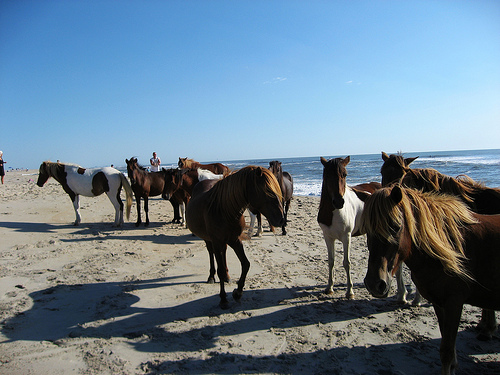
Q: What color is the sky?
A: Blue.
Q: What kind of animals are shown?
A: Horses.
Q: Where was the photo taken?
A: On the beach.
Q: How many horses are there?
A: Ten.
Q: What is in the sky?
A: Nothing.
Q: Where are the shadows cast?
A: To the left.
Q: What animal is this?
A: Horse.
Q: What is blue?
A: Water.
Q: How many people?
A: One.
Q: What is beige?
A: Sand.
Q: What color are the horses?
A: Brown and white.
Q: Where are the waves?
A: In the ocean.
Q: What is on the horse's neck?
A: Mane.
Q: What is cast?
A: Shadows.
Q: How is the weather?
A: Clear.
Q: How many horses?
A: 8.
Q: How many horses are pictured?
A: Nine.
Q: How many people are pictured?
A: Two.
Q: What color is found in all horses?
A: Brown.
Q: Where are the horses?
A: Beach.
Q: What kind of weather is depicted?
A: Sunny and clear.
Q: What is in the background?
A: Ocean.